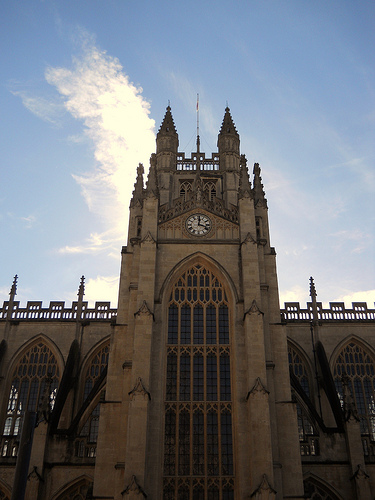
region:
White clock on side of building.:
[190, 215, 209, 234]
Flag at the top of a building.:
[193, 99, 201, 109]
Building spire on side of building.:
[306, 276, 327, 423]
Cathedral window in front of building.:
[160, 260, 232, 497]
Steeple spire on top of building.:
[156, 106, 177, 151]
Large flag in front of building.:
[317, 343, 342, 438]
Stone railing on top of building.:
[177, 153, 218, 170]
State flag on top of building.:
[191, 103, 204, 160]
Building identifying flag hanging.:
[53, 343, 78, 439]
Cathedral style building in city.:
[95, 117, 299, 496]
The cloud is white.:
[81, 77, 134, 150]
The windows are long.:
[175, 353, 232, 484]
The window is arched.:
[15, 326, 74, 455]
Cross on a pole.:
[299, 263, 320, 317]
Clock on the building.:
[175, 204, 221, 252]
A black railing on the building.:
[280, 341, 353, 454]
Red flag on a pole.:
[186, 88, 205, 126]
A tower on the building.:
[211, 94, 246, 166]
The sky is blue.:
[246, 4, 372, 99]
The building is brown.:
[244, 395, 292, 459]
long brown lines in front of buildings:
[168, 299, 188, 473]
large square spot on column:
[108, 356, 154, 379]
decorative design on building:
[157, 390, 256, 422]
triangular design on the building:
[152, 253, 250, 324]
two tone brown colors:
[131, 316, 152, 341]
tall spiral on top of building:
[64, 271, 91, 304]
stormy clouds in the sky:
[301, 242, 346, 265]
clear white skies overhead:
[93, 286, 110, 293]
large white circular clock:
[180, 209, 215, 236]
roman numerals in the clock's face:
[183, 217, 215, 234]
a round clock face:
[185, 212, 211, 236]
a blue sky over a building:
[0, 0, 373, 320]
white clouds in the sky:
[14, 25, 179, 314]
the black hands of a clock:
[195, 216, 207, 228]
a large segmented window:
[0, 332, 66, 463]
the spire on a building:
[153, 99, 181, 152]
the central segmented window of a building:
[154, 249, 238, 496]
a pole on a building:
[307, 274, 319, 319]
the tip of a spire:
[216, 97, 238, 135]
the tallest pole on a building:
[192, 91, 205, 153]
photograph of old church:
[11, 101, 362, 497]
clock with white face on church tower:
[176, 207, 226, 238]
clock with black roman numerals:
[183, 209, 217, 244]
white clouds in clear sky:
[47, 54, 166, 174]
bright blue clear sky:
[208, 22, 354, 86]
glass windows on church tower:
[133, 253, 265, 498]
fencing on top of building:
[0, 298, 136, 321]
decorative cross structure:
[66, 266, 98, 303]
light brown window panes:
[151, 245, 244, 485]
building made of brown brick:
[102, 405, 152, 460]